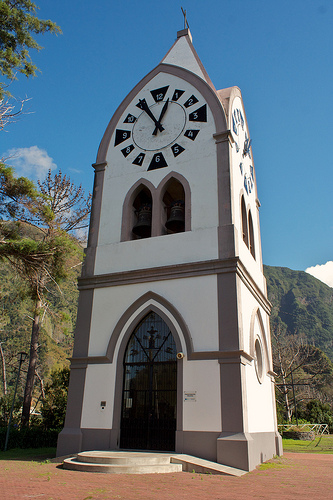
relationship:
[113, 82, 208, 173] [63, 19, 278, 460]
clock on building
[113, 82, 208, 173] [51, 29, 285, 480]
clock on building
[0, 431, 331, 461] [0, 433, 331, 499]
grass on ground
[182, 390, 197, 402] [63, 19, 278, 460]
sign on building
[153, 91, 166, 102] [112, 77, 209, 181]
number on clock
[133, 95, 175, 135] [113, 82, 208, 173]
hands on clock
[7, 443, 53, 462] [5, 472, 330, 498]
shade on ground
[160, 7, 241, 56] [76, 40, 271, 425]
cross on top of tower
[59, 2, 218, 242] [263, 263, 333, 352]
tower in front of hill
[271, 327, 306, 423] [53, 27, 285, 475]
tree behind tower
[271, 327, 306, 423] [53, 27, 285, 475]
tree between tower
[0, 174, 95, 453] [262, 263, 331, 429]
tree between mountain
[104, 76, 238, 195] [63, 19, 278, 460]
clock on building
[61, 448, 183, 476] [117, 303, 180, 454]
step at doorway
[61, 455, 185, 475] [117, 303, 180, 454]
step at doorway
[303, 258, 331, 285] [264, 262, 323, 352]
cloud above hill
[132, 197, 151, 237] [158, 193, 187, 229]
bell left of bell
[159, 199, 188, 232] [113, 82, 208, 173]
bell under clock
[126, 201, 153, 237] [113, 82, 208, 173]
bell under clock